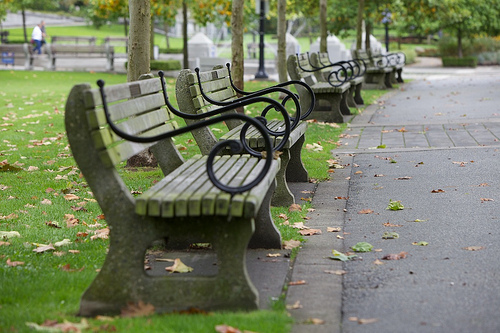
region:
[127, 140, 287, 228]
The seat of a park bench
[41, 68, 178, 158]
The backrest of the park bench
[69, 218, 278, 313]
The bottom base of a park bench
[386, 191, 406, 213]
The green leaf on a paved trail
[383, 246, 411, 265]
The brown leaf on a paved trail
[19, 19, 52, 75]
The person walking on a path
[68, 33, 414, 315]
Several park benches by a walking trail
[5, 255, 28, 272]
The Brown leaf in the grass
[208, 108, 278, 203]
Arm rest on a bench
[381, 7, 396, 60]
A lamp post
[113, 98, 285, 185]
arm rest of a bench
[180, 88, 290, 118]
arm rest of a bench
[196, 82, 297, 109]
arm rest of a bench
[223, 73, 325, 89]
arm rest of a bench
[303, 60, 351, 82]
arm rest of a bench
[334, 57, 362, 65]
arm rest of a bench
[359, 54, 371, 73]
arm rest of a bench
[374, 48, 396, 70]
arm rest of a bench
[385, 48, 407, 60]
arm rest of a bench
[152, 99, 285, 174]
a arm rest of a bench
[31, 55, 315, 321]
a park bench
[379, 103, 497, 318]
a walkway in a park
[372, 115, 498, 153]
bricks on a walkway in a park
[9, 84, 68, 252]
the grassy area of a park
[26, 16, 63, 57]
two people walking through a park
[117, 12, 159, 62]
the trunk of a tree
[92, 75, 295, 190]
ornamental iron on a park bench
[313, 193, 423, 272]
leaves on a cement walkway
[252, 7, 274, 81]
a black lamppost in a park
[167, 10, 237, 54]
a fountain in the distance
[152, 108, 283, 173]
arm of a bench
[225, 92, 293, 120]
arm of a bench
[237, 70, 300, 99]
arm of a bench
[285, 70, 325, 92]
arm of a bench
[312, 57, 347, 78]
arm of a bench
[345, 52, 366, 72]
arm of a bench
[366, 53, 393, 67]
arm of a bench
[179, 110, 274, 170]
arm rest of a bench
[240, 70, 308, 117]
arm rest of a bench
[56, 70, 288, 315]
concrete bench with wooden seat and back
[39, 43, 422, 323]
a row of benches beside the sidewalk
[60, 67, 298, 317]
bench with black metal arm rests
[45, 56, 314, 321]
two benches in front of tree on grass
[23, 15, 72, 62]
people walking in the background of photo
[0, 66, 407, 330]
grass in middle of park next to benches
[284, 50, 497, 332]
side walk next to park benches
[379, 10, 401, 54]
lamp post next to the side walk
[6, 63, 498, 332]
leaves scattered all over the ground in park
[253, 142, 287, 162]
leaf on park bench seat next to side walk